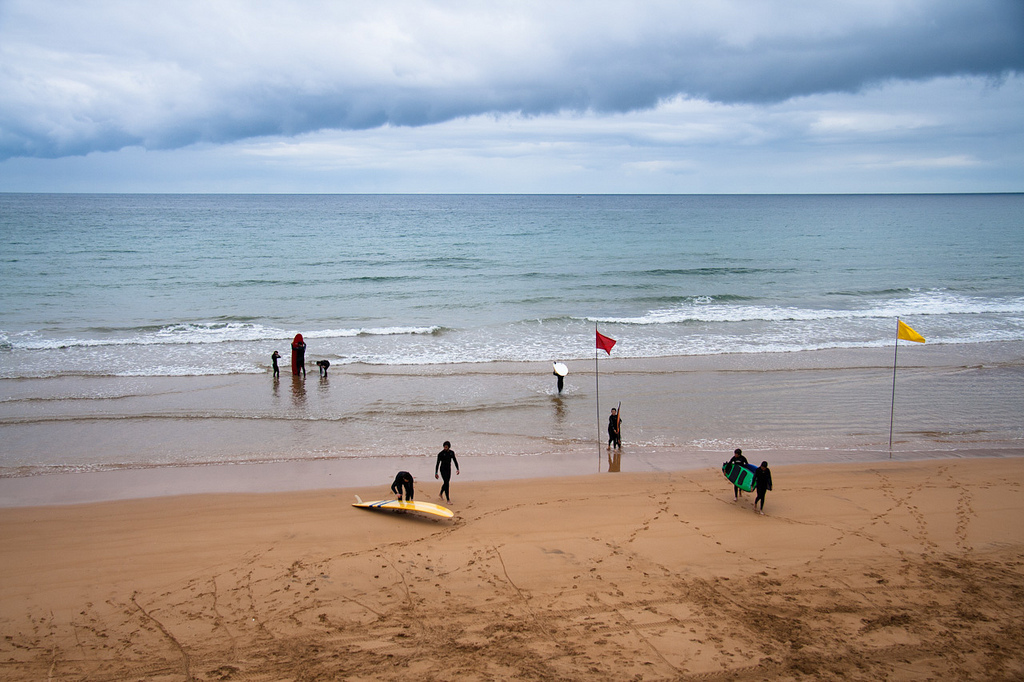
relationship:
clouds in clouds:
[1, 3, 1000, 197] [0, 0, 1022, 195]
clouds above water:
[1, 3, 1000, 197] [2, 194, 1021, 461]